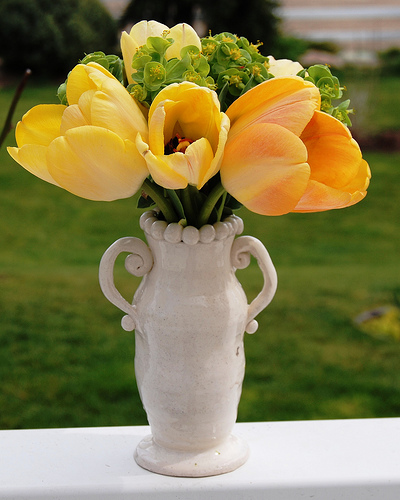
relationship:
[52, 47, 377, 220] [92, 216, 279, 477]
tulips in vase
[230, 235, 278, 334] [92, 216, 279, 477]
handle on vase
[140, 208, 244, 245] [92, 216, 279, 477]
balls on vase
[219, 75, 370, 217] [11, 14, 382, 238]
flower in bouquet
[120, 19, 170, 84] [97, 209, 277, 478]
flowers in vase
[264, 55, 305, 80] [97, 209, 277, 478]
yellow flower in vase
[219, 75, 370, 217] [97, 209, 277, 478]
flower in vase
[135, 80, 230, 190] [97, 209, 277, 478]
flower in vase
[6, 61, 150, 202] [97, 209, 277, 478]
flower in vase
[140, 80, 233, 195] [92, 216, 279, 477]
flower in vase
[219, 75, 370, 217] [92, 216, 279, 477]
flower in vase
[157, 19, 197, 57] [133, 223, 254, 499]
flower in vase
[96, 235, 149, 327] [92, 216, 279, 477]
handle on vase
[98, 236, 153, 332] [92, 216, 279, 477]
handle on vase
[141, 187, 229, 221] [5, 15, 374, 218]
green stems on flowers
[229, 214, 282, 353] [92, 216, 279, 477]
handle on vase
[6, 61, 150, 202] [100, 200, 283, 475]
flower in vase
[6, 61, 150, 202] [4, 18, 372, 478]
flower in a bouquet